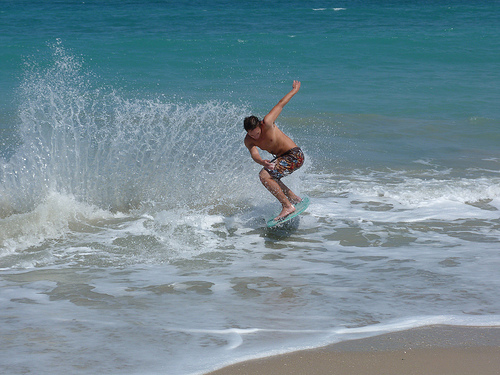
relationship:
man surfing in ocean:
[243, 78, 305, 220] [1, 1, 496, 371]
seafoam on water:
[2, 162, 499, 373] [2, 1, 497, 372]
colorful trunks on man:
[265, 140, 305, 179] [243, 78, 305, 220]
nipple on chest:
[264, 135, 281, 144] [247, 126, 298, 148]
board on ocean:
[267, 196, 309, 228] [1, 1, 497, 374]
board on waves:
[267, 196, 309, 228] [0, 148, 490, 279]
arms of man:
[244, 78, 302, 168] [242, 79, 310, 226]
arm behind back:
[262, 88, 296, 123] [273, 125, 293, 146]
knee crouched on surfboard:
[254, 164, 275, 189] [254, 192, 314, 232]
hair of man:
[242, 115, 262, 132] [243, 81, 303, 219]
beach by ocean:
[207, 320, 497, 372] [2, 3, 497, 333]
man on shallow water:
[243, 78, 305, 220] [2, 134, 497, 370]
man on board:
[243, 78, 305, 220] [264, 195, 305, 230]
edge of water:
[194, 312, 496, 373] [2, 1, 497, 372]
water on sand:
[2, 1, 497, 372] [195, 314, 497, 373]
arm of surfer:
[262, 78, 301, 123] [230, 77, 322, 242]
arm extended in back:
[262, 78, 301, 123] [277, 120, 297, 147]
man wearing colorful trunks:
[243, 78, 305, 220] [264, 148, 305, 179]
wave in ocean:
[2, 154, 495, 253] [2, 3, 497, 333]